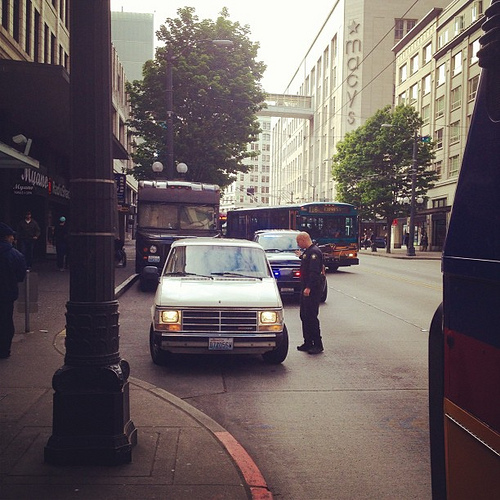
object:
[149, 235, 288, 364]
car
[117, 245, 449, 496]
street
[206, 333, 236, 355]
license plate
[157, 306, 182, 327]
headlight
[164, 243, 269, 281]
windshield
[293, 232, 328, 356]
man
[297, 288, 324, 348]
pants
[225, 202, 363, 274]
bus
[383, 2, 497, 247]
building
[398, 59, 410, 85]
window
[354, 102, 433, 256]
tree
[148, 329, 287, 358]
bumper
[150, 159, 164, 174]
streetlight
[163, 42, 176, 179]
pole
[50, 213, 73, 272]
man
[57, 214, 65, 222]
cap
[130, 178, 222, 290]
truck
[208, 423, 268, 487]
paint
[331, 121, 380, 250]
tree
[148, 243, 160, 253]
headlight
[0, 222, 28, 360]
guy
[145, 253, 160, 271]
tag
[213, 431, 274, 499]
curb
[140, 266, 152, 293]
tire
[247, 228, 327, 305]
car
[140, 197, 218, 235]
windshield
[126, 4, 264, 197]
tree